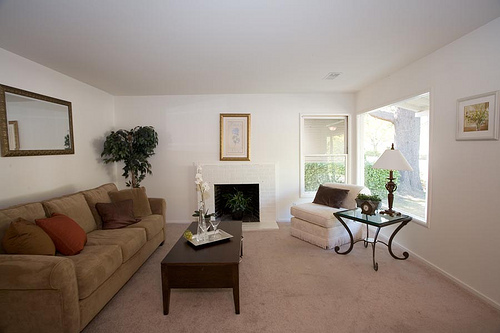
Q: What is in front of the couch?
A: Rectangle table.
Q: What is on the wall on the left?
A: Mirror.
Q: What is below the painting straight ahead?
A: Fireplace.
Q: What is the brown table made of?
A: Wood.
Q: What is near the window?
A: Glass top table.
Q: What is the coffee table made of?
A: Wood.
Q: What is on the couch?
A: Throw pillows.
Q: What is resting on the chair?
A: Throw pillow.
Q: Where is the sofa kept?
A: Living room.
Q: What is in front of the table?
A: Coffee table.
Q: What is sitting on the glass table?
A: Lamp.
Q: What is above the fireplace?
A: Picture.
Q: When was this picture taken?
A: Daytime.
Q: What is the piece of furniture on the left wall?
A: Couch.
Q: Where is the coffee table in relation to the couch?
A: In front of the couch.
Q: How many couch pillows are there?
A: Four.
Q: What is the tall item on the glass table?
A: The lamp.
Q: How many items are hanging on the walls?
A: Three.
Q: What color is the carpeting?
A: Tan.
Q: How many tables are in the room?
A: Two.